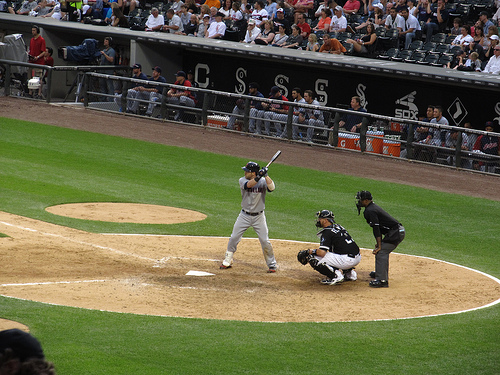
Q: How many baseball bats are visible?
A: One.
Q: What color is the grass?
A: Green.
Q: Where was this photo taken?
A: At a baseball game.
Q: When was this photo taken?
A: Outside, during the daytime.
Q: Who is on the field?
A: Baseball players.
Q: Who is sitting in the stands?
A: People watching a baseball game.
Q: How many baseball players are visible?
A: Three.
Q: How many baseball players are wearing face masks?
A: Two.